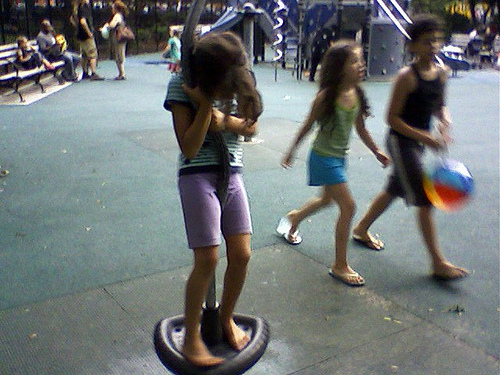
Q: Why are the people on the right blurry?
A: Moving.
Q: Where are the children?
A: Playground.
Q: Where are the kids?
A: Park.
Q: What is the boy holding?
A: A ball.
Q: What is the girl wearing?
A: Purple shorts.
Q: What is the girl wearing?
A: Blue shorts.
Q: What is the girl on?
A: A playground touly.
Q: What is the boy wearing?
A: Black shorts.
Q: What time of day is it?
A: Afternoon.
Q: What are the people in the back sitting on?
A: Bench.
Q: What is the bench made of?
A: Wood.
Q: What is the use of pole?
A: To stand.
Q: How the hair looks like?
A: Curly.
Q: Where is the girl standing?
A: On swing.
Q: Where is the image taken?
A: At park.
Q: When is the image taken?
A: Girls are walking.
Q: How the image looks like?
A: Sad.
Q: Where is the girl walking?
A: The girl is walking at the park.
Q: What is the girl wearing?
A: The girl is wearing flip flops.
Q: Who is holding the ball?
A: A boy is holding a ball.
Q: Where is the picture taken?
A: Playground.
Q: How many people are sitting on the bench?
A: Two.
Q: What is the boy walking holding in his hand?
A: A ball.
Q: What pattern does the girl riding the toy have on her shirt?
A: Striped.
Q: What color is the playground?
A: Blue.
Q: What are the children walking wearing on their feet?
A: Flip flops.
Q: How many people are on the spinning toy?
A: One.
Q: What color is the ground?
A: Green.